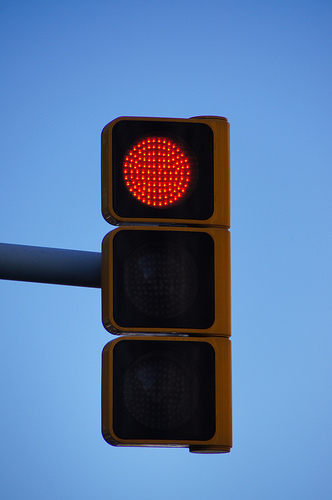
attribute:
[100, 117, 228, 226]
traffic light — red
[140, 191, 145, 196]
light — small, red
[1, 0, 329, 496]
sky — blue, clear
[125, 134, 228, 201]
light — red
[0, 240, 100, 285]
bar — metal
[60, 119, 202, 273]
light — red, circular, small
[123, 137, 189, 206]
light — red, small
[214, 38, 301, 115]
sky — blue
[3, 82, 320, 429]
sky — blue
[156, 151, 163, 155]
lights — red, small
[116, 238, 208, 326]
light — traffic light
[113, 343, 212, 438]
light — traffic light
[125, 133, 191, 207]
red light — small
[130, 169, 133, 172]
pixel — red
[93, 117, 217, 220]
light — red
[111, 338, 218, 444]
bottom light — green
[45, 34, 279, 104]
sky — blue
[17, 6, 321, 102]
sky — blue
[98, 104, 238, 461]
light — red, small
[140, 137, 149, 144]
pixel — red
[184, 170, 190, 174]
pixel — red